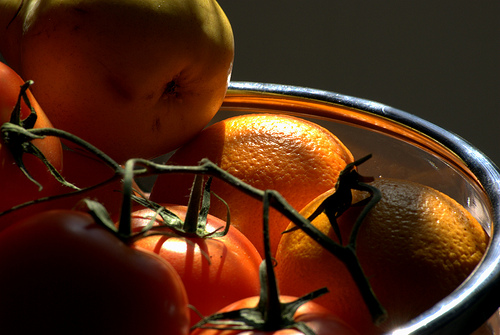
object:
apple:
[21, 0, 235, 163]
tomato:
[1, 63, 65, 229]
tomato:
[1, 208, 189, 334]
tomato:
[111, 204, 265, 333]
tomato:
[187, 293, 361, 334]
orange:
[149, 114, 359, 260]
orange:
[273, 178, 489, 335]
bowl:
[122, 81, 500, 335]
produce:
[1, 1, 490, 334]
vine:
[0, 62, 500, 335]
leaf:
[113, 163, 231, 236]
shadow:
[153, 236, 229, 281]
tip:
[373, 312, 389, 328]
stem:
[158, 74, 182, 103]